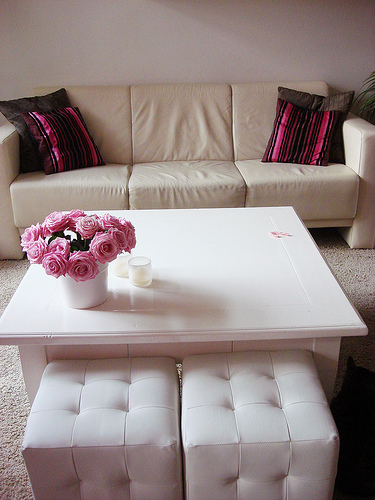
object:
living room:
[0, 0, 374, 499]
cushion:
[128, 152, 248, 210]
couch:
[0, 74, 374, 265]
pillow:
[258, 84, 357, 166]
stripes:
[280, 101, 300, 165]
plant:
[350, 68, 375, 125]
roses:
[42, 249, 69, 281]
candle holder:
[128, 254, 153, 292]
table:
[0, 203, 372, 419]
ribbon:
[280, 226, 293, 244]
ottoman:
[180, 348, 344, 499]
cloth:
[190, 392, 277, 441]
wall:
[4, 1, 372, 83]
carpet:
[325, 240, 369, 287]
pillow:
[0, 85, 103, 176]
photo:
[1, 2, 375, 499]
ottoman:
[21, 353, 180, 498]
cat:
[330, 355, 374, 499]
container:
[60, 257, 108, 310]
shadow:
[106, 284, 212, 327]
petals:
[268, 230, 278, 238]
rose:
[89, 232, 119, 267]